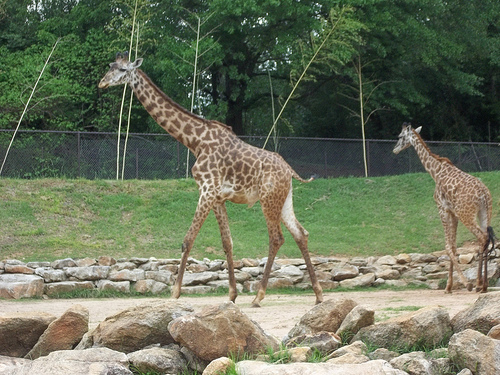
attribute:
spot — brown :
[144, 102, 158, 112]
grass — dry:
[0, 166, 499, 261]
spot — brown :
[180, 120, 194, 137]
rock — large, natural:
[360, 303, 494, 372]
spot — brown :
[162, 109, 174, 124]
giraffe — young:
[392, 121, 499, 294]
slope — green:
[3, 166, 498, 266]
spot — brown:
[201, 123, 224, 153]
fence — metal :
[5, 123, 497, 184]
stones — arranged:
[77, 256, 158, 299]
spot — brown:
[134, 88, 142, 95]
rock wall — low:
[0, 242, 497, 297]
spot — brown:
[183, 135, 200, 150]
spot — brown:
[182, 120, 194, 136]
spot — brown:
[182, 124, 194, 135]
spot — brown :
[170, 114, 184, 124]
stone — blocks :
[315, 255, 402, 289]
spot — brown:
[157, 93, 166, 106]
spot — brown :
[153, 82, 203, 147]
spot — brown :
[178, 137, 245, 182]